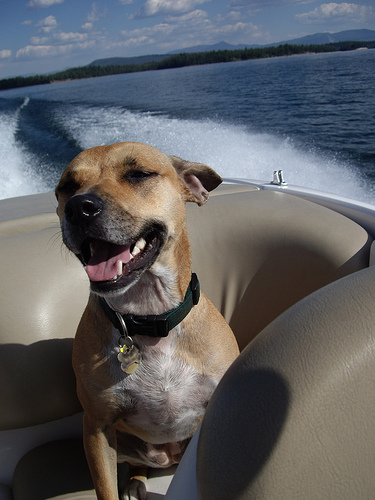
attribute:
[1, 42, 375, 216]
water — blue, calm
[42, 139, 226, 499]
dog — happy, brown, tan, white, sitting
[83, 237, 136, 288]
tongue — pink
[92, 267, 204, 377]
collar — black, green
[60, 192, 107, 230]
nose — black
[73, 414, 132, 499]
leg — brown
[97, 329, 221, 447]
chest — white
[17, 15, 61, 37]
cloud — white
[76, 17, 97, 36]
cloud — white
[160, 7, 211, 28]
cloud — white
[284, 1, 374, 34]
cloud — white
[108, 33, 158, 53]
cloud — white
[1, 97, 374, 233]
ocean surf — white, churning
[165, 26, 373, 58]
hills — hazy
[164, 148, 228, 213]
ear — pointy